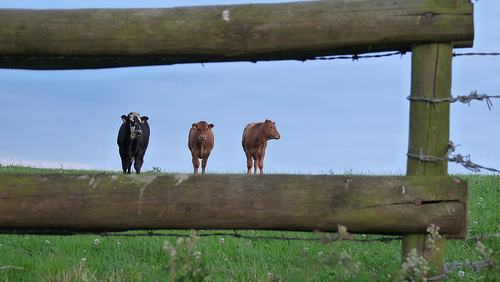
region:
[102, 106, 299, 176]
Three cows standing in the field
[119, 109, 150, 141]
The cow's head is black and white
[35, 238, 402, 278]
The grass is short and green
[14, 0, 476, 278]
The gate is wooden with barbwire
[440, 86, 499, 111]
The barbwire is tied up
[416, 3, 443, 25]
The nail inside the wood holding it together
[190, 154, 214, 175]
The leg's of the cow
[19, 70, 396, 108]
The shy is clear and blue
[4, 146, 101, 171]
A white cloud in the distance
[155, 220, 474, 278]
Flower buds coming out of the ground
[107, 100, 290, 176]
three cows standing in a row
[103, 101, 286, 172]
cows standing in the grass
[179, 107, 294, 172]
two light brown cows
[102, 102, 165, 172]
one black cow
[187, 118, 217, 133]
ears on either side of the head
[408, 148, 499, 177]
wire wrapped around the wooden post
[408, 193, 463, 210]
black slit in the post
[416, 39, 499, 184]
row of three wires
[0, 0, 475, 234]
two wooden posts running parallel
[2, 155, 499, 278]
green grass on the ground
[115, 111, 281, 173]
three cows standing in a pasture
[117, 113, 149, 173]
a black cow with a black and white face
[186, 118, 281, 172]
two brown cows standing in the pasture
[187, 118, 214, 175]
a brown cow between a brown and black cow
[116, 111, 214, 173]
a black cow standing beside a brown cow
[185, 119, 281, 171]
a brown cow standing beside another brown cow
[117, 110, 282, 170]
black and brown cows standing behind a fence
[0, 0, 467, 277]
a wooden and barbwire fence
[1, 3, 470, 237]
two wooden posts connected to a wood pole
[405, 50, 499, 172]
barbwire tied to the wood pole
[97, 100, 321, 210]
three cows in the field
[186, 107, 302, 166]
two cows are brown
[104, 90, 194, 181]
the cow is black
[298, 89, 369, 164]
the sky is clear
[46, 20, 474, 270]
cows in a field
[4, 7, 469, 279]
cows in a green field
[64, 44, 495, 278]
cows in an area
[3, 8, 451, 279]
cows in a green area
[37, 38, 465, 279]
three cows in a field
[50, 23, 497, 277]
two cows in a field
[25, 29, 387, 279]
two cows in a grass field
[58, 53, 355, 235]
a black cow in a field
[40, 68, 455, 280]
a black cow two brown cows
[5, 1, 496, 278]
cows behind a fence